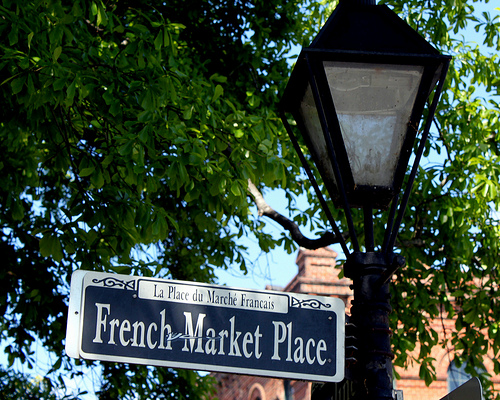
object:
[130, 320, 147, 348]
letter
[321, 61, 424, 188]
glass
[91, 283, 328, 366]
lettering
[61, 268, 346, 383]
sign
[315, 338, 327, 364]
white letter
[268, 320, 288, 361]
letter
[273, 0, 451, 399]
street light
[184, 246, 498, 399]
brick building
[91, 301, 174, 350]
french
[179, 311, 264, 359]
market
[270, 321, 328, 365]
place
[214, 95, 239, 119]
leaves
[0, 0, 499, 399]
tree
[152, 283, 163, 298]
la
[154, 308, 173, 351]
letter